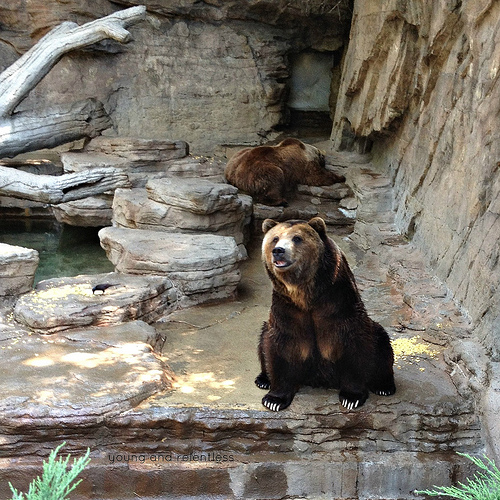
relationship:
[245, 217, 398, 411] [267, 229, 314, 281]
bear has face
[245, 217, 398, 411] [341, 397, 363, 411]
bear has claws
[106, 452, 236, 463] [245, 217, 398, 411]
text by bear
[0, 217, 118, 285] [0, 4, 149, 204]
water under wood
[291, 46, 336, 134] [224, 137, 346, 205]
cave behind bear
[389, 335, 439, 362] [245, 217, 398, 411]
food by bear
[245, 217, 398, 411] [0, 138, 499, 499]
bear on rocks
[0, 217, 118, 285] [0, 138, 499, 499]
water in rocks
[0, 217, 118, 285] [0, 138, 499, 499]
water on rocks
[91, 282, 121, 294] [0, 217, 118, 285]
bird near water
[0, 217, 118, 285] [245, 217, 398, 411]
water near bear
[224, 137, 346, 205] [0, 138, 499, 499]
bear on rocks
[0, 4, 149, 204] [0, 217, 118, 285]
wood above water